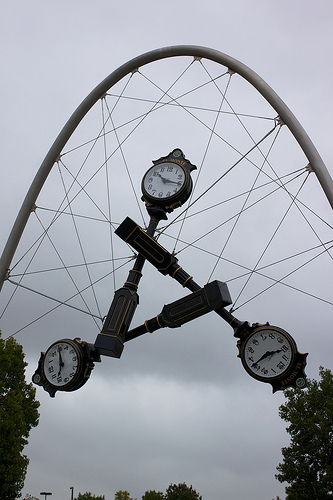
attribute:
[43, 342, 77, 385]
clock — gold accents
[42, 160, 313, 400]
clocks — three, hanging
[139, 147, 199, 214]
clock face — white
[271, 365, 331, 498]
tree — green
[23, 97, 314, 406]
clocks — hanging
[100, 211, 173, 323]
pole — metal 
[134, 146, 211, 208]
clock — small 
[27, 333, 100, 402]
clocks — say the time is 10:15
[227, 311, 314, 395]
clocks — say the time is 10:15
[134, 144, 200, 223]
clocks — say the time is 10:15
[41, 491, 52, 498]
light — tall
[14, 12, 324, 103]
sky — overcast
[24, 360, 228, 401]
light sky — blue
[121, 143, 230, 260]
clock — 10:15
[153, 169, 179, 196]
face — White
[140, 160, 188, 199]
clock — slanted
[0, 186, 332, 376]
sky — blue gray 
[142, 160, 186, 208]
clock — small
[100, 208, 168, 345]
pole — metal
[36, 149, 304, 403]
clocks — Three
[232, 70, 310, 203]
bar — Metal 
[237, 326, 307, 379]
clock. — design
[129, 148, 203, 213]
clock — hanging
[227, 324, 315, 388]
clock — hanging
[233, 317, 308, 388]
clock — hanging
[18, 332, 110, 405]
clock — hanging